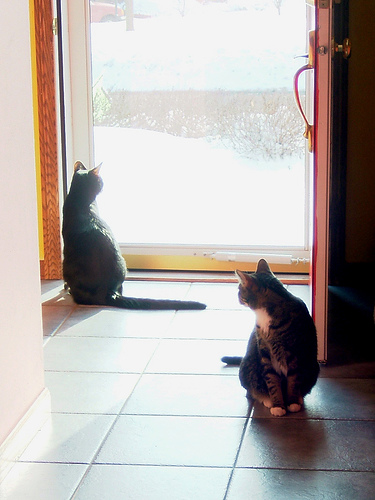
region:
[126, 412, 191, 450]
Small part of the tiled floor in the house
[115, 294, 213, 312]
Black tail of the second cat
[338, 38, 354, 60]
A golden door knob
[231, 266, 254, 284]
Left ear of the first cat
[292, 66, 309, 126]
Red door handle on door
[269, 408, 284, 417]
Right white paw of cat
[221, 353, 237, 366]
Black tail of the first cat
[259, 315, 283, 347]
Medium part of the white, gray, and black sin of the first cat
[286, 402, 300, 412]
Left white paw of the first cat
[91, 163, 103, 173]
Right ear of the second cat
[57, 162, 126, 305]
this is a cat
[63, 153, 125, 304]
the cat is staring outside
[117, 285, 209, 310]
this is the tail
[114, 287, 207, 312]
the tail is long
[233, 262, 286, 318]
the head is facing behind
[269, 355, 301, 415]
these are the fore legs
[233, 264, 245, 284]
this is the ear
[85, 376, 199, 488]
the floor is tiled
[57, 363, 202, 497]
the tiles are white in color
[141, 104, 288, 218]
this is the window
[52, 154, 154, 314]
black color cat seeing outside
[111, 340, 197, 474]
square shape floor tiles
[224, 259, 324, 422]
a cat looking backside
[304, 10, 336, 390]
wooden door of the entrance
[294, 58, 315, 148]
handle of the door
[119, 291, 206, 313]
tail of the cat in the floor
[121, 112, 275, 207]
a place full of snow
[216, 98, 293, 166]
plants covering full of snow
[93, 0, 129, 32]
a car parked in the snow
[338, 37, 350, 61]
handle in the door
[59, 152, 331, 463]
cat's looking out the door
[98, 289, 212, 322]
cat's tail on floor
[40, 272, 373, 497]
the floor is tiled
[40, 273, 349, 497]
light shining on the floor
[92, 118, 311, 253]
snow on ground outside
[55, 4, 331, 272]
light shining through the door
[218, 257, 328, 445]
cat is gray black and white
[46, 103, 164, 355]
cat sitting in the doorway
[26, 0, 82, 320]
door frame made of wood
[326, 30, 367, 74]
door knob is gold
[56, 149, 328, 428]
two cats on the floor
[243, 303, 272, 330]
white patch on cat's neck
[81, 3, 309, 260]
a large window in door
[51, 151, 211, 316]
one cat sitting and looking out the window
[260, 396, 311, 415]
white paws of cat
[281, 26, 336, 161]
brass door handle on door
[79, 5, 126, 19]
a car parked on the road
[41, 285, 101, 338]
shadow of cat on floor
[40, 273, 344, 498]
a tile floor under cats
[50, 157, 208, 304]
a black cat in doorway